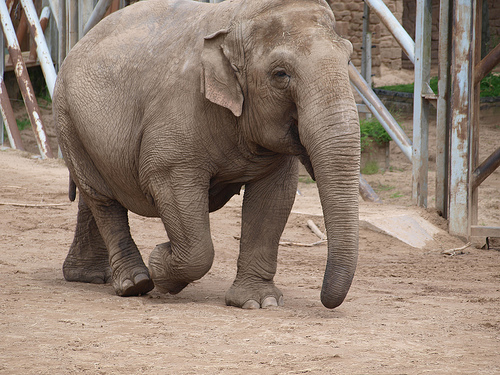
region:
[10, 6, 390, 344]
large grey elephant on dirt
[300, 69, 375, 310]
fat trunk of elephant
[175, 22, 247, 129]
small ear of elephant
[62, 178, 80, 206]
small grey tail of elephant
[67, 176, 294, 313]
grey legs of elephant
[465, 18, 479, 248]
rusted brown metal frame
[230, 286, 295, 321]
large white feet of elephant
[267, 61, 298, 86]
large black eye of elephant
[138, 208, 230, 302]
bent leg of animal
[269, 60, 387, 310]
elephant has long trunk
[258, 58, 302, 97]
elephant has black eye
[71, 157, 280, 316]
elephant has 4 legs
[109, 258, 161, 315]
elephant has large toenails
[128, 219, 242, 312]
elephants foot off ground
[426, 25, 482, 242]
a rusted side bar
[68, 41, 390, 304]
elephant is walking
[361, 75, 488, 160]
green grass in background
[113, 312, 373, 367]
ground is only dirt no plants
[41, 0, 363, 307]
Gray elephant walking in dirt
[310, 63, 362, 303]
Long gray elephant trunk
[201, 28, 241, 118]
Floppy gray elephant ear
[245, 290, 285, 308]
Toes on elephant's foot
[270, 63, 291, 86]
Eye in side of elephant's head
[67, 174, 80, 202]
Tip of elephant's tail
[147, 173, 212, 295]
Bent front leg on elephant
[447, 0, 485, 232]
Rusty metal gate post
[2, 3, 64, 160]
Rusted metal poles for fence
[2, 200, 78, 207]
Dead stick on ground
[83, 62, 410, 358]
an elephant standing outside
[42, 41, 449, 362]
a large elphnat walking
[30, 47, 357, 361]
an elephant walking on dirt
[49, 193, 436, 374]
a field of dirt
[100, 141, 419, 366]
a dirt field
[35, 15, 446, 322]
an elephant in an area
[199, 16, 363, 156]
head of an elephant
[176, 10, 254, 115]
ear of an elephant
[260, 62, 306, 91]
eye of an elephant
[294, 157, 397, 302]
nose of an elephant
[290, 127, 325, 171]
mouth of an elephant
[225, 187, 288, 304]
leg of an elephant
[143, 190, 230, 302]
leg of an elephant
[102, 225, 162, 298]
leg of an elephant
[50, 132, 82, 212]
tail of an elephant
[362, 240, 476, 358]
the dirt is brown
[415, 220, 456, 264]
dirt is covering the sidewalk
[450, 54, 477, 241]
rust is on the column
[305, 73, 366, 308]
the trunk is wrinkled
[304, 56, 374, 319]
the trunk is touching the gorund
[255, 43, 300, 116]
wrinkles around the eye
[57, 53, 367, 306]
the animal is a elephant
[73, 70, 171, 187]
wrinkles on the elephant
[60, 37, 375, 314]
the elephant is walking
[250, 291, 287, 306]
nails on the hoof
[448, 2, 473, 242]
A long metal pole.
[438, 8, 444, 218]
A long metal pole.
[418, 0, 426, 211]
A long metal pole.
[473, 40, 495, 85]
A long metal pole.